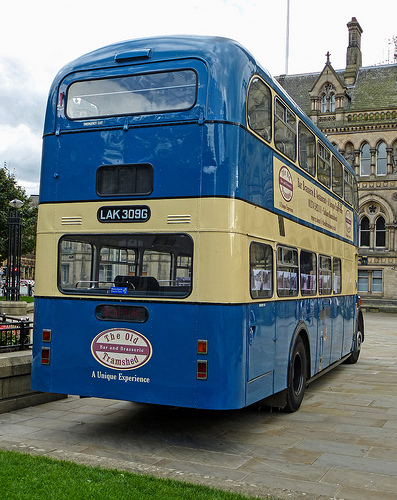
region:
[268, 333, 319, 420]
black bus tire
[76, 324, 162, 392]
logo on the back side of the bus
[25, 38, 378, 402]
blue and tan double decker bus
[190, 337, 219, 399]
back right bus lights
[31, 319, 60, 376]
back left bus lights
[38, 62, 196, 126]
back window on the bus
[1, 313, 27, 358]
black metal gate around flowers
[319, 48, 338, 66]
cross on top of a building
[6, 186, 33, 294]
street light on a pole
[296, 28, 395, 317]
large church in back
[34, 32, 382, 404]
Double decker blue bus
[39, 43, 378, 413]
Blue and cream bus is double decker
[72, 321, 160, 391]
Red and white sign on back of bus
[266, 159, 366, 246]
Long sign on side of bus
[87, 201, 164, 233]
Letters and numbers on back of bus in black and white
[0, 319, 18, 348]
Red flowers next to bus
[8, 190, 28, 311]
A lampost with white light on top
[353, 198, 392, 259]
Two arch windows and a flower window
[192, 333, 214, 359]
Red taillight on right side rear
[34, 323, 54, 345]
Red taillight on left side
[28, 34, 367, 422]
a blue and yellow bus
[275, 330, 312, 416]
the tire is black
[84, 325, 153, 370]
an oval sign on the back of the bus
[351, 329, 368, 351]
a chrome hub cap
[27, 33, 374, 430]
the bus is large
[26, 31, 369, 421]
an old double decked bus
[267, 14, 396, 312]
an old stone church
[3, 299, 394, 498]
a flagstone parking lot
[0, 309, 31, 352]
a short black iron fence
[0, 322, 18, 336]
red flowers behind the fence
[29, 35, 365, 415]
a blue red and tan double decker bus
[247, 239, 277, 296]
the window of a double decker bus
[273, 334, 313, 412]
the wheel of a double decker bus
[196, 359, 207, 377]
the tail light of a double decker bus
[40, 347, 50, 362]
the tail light of a double decker bus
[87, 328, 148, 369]
the logo of a double decker bus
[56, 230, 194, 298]
the back window of a double decker bus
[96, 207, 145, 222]
the black destination marquee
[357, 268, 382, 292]
the window on the building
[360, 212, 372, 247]
the window on the building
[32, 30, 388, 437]
A double decker bus outside a building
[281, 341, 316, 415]
Back black wheel of bus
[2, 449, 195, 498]
Small patch of grass behind bus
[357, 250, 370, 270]
Side mirror on right side of bus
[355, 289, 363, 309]
Turn indicator on right side of bus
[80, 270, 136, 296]
Silver hand rail inside bus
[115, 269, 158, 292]
Head rest of seat inside bus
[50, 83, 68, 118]
Red handle on upper window of bus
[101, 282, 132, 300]
Blue and white sticker on back window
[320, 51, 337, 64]
Cross on top of peak